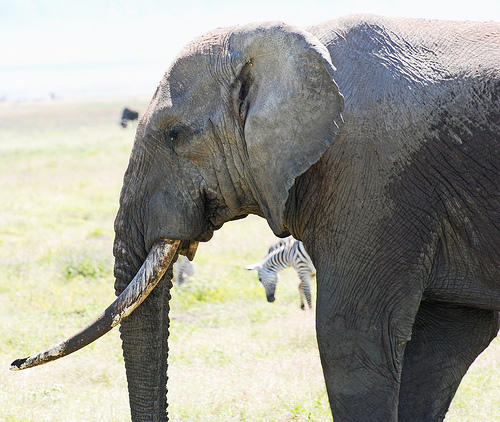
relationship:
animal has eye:
[8, 15, 499, 422] [135, 123, 192, 153]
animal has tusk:
[8, 15, 499, 422] [3, 233, 204, 375]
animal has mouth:
[8, 15, 499, 422] [181, 200, 276, 251]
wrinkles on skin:
[334, 60, 478, 311] [212, 35, 492, 252]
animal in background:
[231, 232, 327, 294] [0, 7, 497, 162]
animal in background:
[110, 102, 152, 129] [0, 7, 497, 162]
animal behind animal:
[240, 235, 326, 311] [8, 15, 499, 422]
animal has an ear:
[8, 15, 499, 422] [242, 22, 347, 238]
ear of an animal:
[242, 22, 347, 238] [8, 15, 499, 422]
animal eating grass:
[240, 235, 326, 311] [194, 277, 250, 334]